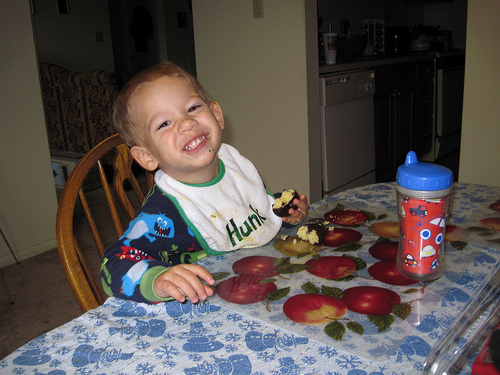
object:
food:
[270, 187, 302, 218]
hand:
[276, 192, 308, 227]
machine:
[317, 67, 381, 194]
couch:
[37, 67, 120, 164]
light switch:
[249, 0, 265, 21]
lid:
[393, 149, 453, 192]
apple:
[211, 272, 275, 304]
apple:
[230, 253, 276, 279]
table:
[0, 180, 499, 374]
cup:
[393, 149, 455, 281]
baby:
[97, 60, 309, 306]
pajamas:
[97, 187, 209, 307]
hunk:
[223, 204, 270, 248]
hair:
[111, 56, 214, 152]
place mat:
[187, 197, 489, 366]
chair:
[54, 131, 157, 323]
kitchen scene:
[0, 1, 499, 374]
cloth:
[1, 182, 499, 373]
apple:
[367, 258, 416, 287]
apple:
[304, 253, 356, 280]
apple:
[316, 226, 362, 250]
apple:
[325, 207, 365, 228]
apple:
[366, 219, 403, 241]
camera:
[0, 2, 499, 374]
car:
[410, 213, 447, 246]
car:
[401, 251, 418, 268]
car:
[406, 203, 427, 218]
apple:
[280, 290, 347, 325]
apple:
[339, 284, 401, 316]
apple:
[368, 235, 401, 263]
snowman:
[181, 352, 253, 375]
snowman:
[182, 319, 224, 353]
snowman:
[244, 328, 310, 352]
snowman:
[106, 315, 165, 339]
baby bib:
[153, 144, 286, 256]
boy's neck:
[158, 155, 221, 187]